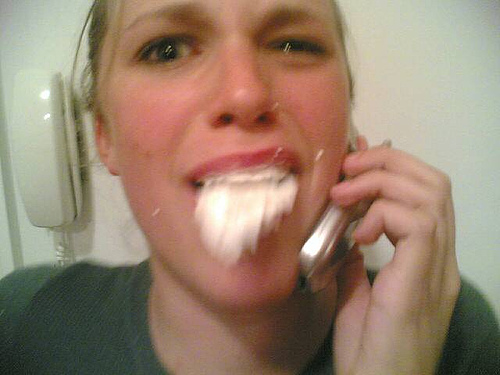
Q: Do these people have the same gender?
A: Yes, all the people are female.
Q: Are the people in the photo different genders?
A: No, all the people are female.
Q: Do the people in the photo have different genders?
A: No, all the people are female.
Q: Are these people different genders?
A: No, all the people are female.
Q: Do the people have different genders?
A: No, all the people are female.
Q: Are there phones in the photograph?
A: Yes, there is a phone.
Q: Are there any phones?
A: Yes, there is a phone.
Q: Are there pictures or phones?
A: Yes, there is a phone.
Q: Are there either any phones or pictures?
A: Yes, there is a phone.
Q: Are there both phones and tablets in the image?
A: No, there is a phone but no tablets.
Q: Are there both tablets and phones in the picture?
A: No, there is a phone but no tablets.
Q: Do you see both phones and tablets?
A: No, there is a phone but no tablets.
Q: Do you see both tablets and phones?
A: No, there is a phone but no tablets.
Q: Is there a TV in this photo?
A: No, there are no televisions.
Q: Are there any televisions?
A: No, there are no televisions.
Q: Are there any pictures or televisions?
A: No, there are no televisions or pictures.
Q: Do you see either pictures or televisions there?
A: No, there are no televisions or pictures.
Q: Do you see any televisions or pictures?
A: No, there are no televisions or pictures.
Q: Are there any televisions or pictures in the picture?
A: No, there are no televisions or pictures.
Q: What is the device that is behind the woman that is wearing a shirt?
A: The device is a phone.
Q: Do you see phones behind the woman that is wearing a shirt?
A: Yes, there is a phone behind the woman.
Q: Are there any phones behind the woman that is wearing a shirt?
A: Yes, there is a phone behind the woman.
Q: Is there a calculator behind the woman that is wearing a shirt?
A: No, there is a phone behind the woman.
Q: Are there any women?
A: Yes, there is a woman.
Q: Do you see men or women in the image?
A: Yes, there is a woman.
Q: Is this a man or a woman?
A: This is a woman.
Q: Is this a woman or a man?
A: This is a woman.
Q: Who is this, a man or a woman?
A: This is a woman.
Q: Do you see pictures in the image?
A: No, there are no pictures.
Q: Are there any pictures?
A: No, there are no pictures.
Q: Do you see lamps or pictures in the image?
A: No, there are no pictures or lamps.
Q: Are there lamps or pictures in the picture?
A: No, there are no pictures or lamps.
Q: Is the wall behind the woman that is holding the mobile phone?
A: Yes, the wall is behind the woman.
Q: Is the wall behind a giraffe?
A: No, the wall is behind the woman.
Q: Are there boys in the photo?
A: No, there are no boys.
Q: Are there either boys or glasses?
A: No, there are no boys or glasses.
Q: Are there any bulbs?
A: No, there are no bulbs.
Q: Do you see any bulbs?
A: No, there are no bulbs.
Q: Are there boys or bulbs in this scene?
A: No, there are no bulbs or boys.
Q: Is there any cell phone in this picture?
A: Yes, there is a cell phone.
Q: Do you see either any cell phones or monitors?
A: Yes, there is a cell phone.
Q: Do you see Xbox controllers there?
A: No, there are no Xbox controllers.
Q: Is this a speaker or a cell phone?
A: This is a cell phone.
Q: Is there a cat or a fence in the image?
A: No, there are no fences or cats.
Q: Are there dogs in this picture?
A: No, there are no dogs.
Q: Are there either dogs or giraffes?
A: No, there are no dogs or giraffes.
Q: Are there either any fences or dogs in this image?
A: No, there are no dogs or fences.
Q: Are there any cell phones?
A: Yes, there is a cell phone.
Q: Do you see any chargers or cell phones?
A: Yes, there is a cell phone.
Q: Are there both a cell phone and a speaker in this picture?
A: No, there is a cell phone but no speakers.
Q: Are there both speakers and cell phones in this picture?
A: No, there is a cell phone but no speakers.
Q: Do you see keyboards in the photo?
A: No, there are no keyboards.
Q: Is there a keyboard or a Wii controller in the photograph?
A: No, there are no keyboards or Wii controllers.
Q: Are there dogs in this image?
A: No, there are no dogs.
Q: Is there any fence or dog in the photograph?
A: No, there are no dogs or fences.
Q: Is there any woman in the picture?
A: Yes, there is a woman.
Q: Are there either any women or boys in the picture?
A: Yes, there is a woman.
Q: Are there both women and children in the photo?
A: No, there is a woman but no children.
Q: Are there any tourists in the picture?
A: No, there are no tourists.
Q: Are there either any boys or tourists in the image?
A: No, there are no tourists or boys.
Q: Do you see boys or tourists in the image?
A: No, there are no tourists or boys.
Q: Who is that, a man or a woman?
A: That is a woman.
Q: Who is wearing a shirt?
A: The woman is wearing a shirt.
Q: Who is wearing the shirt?
A: The woman is wearing a shirt.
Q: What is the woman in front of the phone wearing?
A: The woman is wearing a shirt.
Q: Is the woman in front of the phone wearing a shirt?
A: Yes, the woman is wearing a shirt.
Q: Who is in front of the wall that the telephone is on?
A: The woman is in front of the wall.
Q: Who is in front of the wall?
A: The woman is in front of the wall.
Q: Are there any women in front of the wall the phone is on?
A: Yes, there is a woman in front of the wall.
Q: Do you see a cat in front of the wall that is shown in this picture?
A: No, there is a woman in front of the wall.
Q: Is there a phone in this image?
A: Yes, there is a phone.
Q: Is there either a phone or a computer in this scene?
A: Yes, there is a phone.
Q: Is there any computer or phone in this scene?
A: Yes, there is a phone.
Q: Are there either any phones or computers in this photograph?
A: Yes, there is a phone.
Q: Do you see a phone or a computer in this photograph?
A: Yes, there is a phone.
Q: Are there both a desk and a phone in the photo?
A: No, there is a phone but no desks.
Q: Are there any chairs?
A: No, there are no chairs.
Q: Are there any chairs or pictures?
A: No, there are no chairs or pictures.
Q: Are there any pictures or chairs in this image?
A: No, there are no chairs or pictures.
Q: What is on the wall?
A: The phone is on the wall.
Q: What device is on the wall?
A: The device is a phone.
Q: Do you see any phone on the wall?
A: Yes, there is a phone on the wall.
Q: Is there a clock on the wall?
A: No, there is a phone on the wall.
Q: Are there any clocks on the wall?
A: No, there is a phone on the wall.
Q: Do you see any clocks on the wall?
A: No, there is a phone on the wall.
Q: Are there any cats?
A: No, there are no cats.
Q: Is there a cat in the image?
A: No, there are no cats.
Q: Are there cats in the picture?
A: No, there are no cats.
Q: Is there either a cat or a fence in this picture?
A: No, there are no cats or fences.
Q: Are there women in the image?
A: Yes, there is a woman.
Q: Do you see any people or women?
A: Yes, there is a woman.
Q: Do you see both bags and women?
A: No, there is a woman but no bags.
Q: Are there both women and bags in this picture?
A: No, there is a woman but no bags.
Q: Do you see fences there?
A: No, there are no fences.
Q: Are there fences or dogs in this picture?
A: No, there are no fences or dogs.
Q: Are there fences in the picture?
A: No, there are no fences.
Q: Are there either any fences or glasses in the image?
A: No, there are no fences or glasses.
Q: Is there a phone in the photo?
A: Yes, there is a phone.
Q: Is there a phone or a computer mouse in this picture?
A: Yes, there is a phone.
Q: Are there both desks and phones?
A: No, there is a phone but no desks.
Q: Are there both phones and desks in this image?
A: No, there is a phone but no desks.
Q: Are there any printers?
A: No, there are no printers.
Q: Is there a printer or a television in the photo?
A: No, there are no printers or televisions.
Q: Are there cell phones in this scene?
A: Yes, there is a cell phone.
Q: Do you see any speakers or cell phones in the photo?
A: Yes, there is a cell phone.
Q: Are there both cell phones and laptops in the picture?
A: No, there is a cell phone but no laptops.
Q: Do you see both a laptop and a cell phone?
A: No, there is a cell phone but no laptops.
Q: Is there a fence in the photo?
A: No, there are no fences.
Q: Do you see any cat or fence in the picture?
A: No, there are no fences or cats.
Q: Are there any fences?
A: No, there are no fences.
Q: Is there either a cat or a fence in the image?
A: No, there are no fences or cats.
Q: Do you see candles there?
A: No, there are no candles.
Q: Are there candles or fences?
A: No, there are no candles or fences.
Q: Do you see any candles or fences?
A: No, there are no candles or fences.